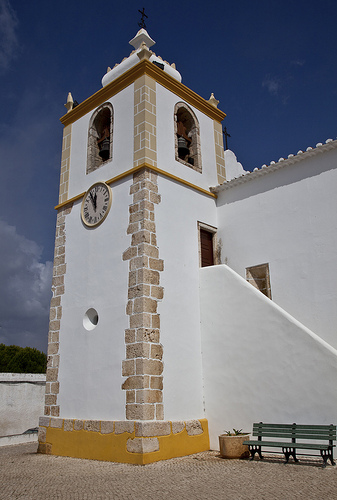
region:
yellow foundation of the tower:
[38, 416, 209, 463]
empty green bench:
[246, 421, 335, 468]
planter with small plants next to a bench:
[218, 428, 249, 459]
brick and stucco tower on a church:
[38, 3, 217, 461]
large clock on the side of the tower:
[81, 182, 110, 226]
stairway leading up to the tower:
[203, 266, 336, 454]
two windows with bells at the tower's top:
[89, 104, 202, 170]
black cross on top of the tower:
[136, 7, 148, 29]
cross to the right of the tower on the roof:
[223, 126, 231, 149]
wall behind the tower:
[0, 372, 44, 443]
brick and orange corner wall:
[36, 407, 217, 468]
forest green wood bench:
[245, 416, 334, 470]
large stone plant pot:
[216, 423, 255, 460]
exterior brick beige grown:
[179, 464, 260, 494]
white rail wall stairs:
[199, 262, 334, 378]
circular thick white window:
[76, 305, 111, 340]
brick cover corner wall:
[123, 176, 175, 422]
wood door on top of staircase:
[194, 211, 328, 358]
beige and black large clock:
[77, 180, 117, 231]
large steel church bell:
[170, 99, 218, 178]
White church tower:
[47, 44, 218, 380]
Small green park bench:
[247, 412, 336, 461]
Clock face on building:
[78, 184, 112, 224]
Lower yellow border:
[44, 412, 212, 465]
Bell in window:
[171, 98, 206, 170]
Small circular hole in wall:
[81, 297, 103, 333]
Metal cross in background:
[220, 124, 233, 151]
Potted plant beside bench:
[222, 416, 247, 459]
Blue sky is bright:
[162, 7, 335, 84]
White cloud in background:
[2, 217, 53, 315]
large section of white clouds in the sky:
[8, 223, 46, 317]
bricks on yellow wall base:
[107, 431, 158, 456]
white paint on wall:
[61, 348, 121, 386]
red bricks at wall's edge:
[131, 329, 162, 407]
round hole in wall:
[69, 301, 123, 344]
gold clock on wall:
[70, 175, 117, 233]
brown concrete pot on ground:
[214, 427, 250, 455]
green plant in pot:
[214, 415, 246, 440]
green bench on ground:
[251, 413, 332, 469]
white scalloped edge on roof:
[217, 155, 307, 177]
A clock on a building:
[78, 177, 125, 224]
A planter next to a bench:
[209, 423, 255, 461]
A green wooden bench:
[247, 419, 336, 470]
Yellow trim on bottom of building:
[28, 410, 229, 467]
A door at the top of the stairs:
[195, 221, 226, 275]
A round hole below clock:
[78, 293, 108, 336]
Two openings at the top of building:
[76, 90, 210, 175]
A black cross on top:
[128, 6, 164, 32]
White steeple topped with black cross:
[86, 24, 207, 78]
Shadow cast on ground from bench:
[238, 450, 336, 465]